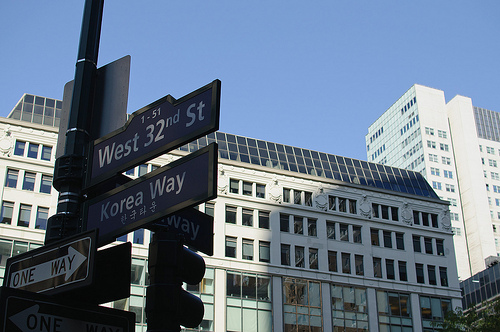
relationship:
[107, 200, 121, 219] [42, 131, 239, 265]
letter on sign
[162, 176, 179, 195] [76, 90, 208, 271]
letter on sign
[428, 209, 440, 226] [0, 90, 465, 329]
window on building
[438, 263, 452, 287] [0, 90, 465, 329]
window on building